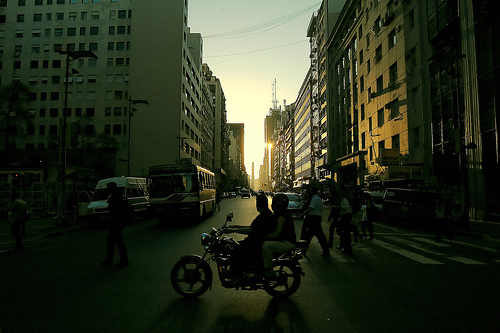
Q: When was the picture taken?
A: Daytime.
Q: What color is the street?
A: Black.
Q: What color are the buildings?
A: White and yellow.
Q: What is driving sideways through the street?
A: The motorcycle.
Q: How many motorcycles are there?
A: One.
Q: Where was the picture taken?
A: In a city street.